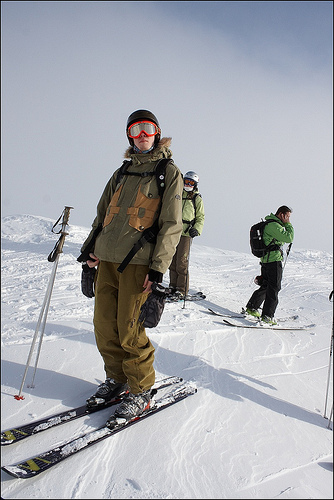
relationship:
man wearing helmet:
[79, 83, 182, 430] [124, 106, 158, 153]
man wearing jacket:
[79, 110, 183, 395] [75, 147, 199, 269]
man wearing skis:
[79, 83, 182, 430] [0, 373, 199, 478]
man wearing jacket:
[246, 202, 298, 324] [260, 213, 291, 258]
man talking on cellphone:
[79, 110, 183, 395] [278, 209, 285, 221]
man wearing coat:
[244, 205, 294, 326] [257, 214, 295, 264]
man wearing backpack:
[244, 205, 294, 326] [245, 215, 284, 260]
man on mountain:
[79, 110, 183, 395] [3, 210, 330, 492]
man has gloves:
[79, 110, 183, 395] [79, 260, 173, 321]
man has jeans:
[79, 110, 183, 395] [93, 261, 155, 393]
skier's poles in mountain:
[14, 207, 72, 400] [3, 210, 330, 492]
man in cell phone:
[244, 205, 294, 326] [278, 211, 286, 219]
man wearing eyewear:
[79, 110, 183, 395] [127, 122, 161, 139]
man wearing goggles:
[79, 83, 182, 430] [126, 119, 161, 141]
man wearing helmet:
[79, 83, 182, 430] [116, 104, 171, 126]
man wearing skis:
[79, 83, 182, 430] [0, 383, 197, 480]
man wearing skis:
[79, 83, 182, 430] [0, 374, 184, 448]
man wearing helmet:
[165, 173, 202, 299] [184, 171, 198, 190]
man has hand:
[246, 202, 298, 324] [281, 214, 290, 221]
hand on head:
[281, 214, 290, 221] [273, 202, 293, 222]